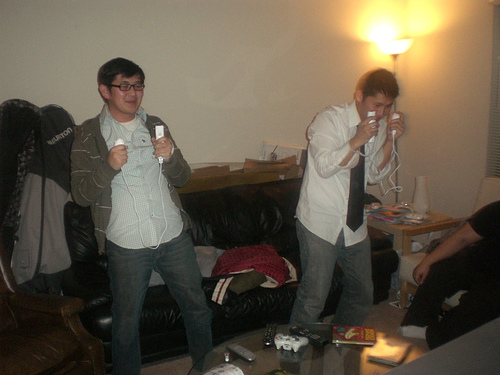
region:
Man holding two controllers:
[69, 38, 254, 374]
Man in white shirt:
[283, 54, 436, 354]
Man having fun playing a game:
[72, 50, 269, 373]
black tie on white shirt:
[337, 121, 398, 269]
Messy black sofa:
[14, 138, 401, 366]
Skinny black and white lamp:
[371, 21, 440, 232]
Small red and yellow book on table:
[330, 317, 386, 353]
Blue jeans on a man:
[87, 222, 254, 374]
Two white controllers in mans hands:
[362, 110, 432, 227]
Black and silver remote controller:
[222, 339, 260, 371]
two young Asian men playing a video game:
[31, 37, 432, 314]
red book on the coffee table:
[328, 323, 378, 350]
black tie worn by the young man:
[345, 165, 369, 233]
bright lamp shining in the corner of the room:
[353, 16, 428, 66]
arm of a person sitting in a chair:
[397, 207, 493, 290]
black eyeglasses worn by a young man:
[103, 80, 147, 94]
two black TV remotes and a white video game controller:
[253, 317, 327, 354]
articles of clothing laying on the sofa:
[196, 244, 305, 310]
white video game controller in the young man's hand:
[146, 116, 172, 168]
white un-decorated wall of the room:
[154, 22, 307, 128]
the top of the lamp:
[378, 35, 413, 62]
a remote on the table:
[264, 321, 274, 347]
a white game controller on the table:
[273, 331, 308, 353]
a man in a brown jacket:
[67, 55, 215, 366]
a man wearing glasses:
[66, 55, 213, 361]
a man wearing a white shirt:
[300, 68, 402, 328]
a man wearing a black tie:
[294, 68, 397, 325]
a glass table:
[192, 321, 419, 373]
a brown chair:
[0, 270, 104, 373]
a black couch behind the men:
[51, 183, 398, 328]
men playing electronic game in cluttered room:
[58, 57, 403, 362]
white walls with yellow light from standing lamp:
[5, 5, 490, 206]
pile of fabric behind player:
[1, 95, 71, 281]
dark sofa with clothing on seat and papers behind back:
[67, 155, 392, 361]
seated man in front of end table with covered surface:
[371, 185, 491, 335]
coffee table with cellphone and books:
[155, 310, 430, 370]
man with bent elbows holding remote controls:
[310, 65, 400, 170]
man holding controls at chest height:
[65, 55, 185, 200]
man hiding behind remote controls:
[305, 65, 405, 166]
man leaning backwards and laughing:
[67, 52, 194, 288]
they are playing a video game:
[58, 34, 453, 374]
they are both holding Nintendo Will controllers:
[41, 20, 448, 367]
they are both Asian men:
[8, 18, 468, 372]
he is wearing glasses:
[58, 36, 250, 371]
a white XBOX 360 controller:
[266, 325, 321, 364]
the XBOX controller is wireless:
[261, 313, 326, 373]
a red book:
[325, 313, 392, 353]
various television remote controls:
[212, 312, 337, 372]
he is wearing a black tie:
[285, 45, 445, 363]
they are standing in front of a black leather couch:
[56, 166, 453, 365]